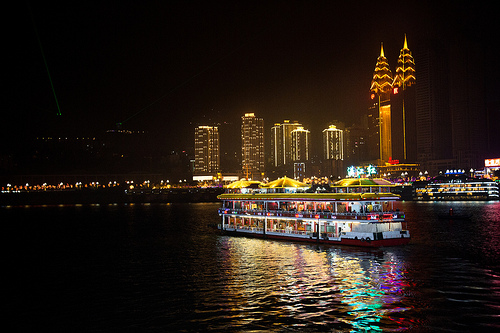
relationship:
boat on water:
[205, 157, 397, 242] [116, 240, 300, 318]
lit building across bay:
[189, 121, 220, 175] [4, 200, 497, 324]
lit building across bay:
[239, 110, 264, 178] [4, 200, 497, 324]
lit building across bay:
[269, 116, 281, 173] [4, 200, 497, 324]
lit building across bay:
[287, 123, 308, 162] [4, 200, 497, 324]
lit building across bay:
[322, 124, 344, 159] [4, 200, 497, 324]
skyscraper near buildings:
[323, 31, 427, 138] [144, 49, 423, 189]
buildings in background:
[183, 33, 439, 182] [26, 143, 482, 204]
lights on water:
[287, 241, 419, 331] [2, 233, 497, 330]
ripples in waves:
[169, 230, 499, 325] [225, 237, 424, 331]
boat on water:
[210, 168, 413, 251] [2, 204, 498, 331]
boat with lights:
[210, 168, 413, 251] [210, 167, 402, 325]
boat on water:
[210, 168, 413, 251] [173, 248, 415, 314]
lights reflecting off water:
[220, 170, 393, 195] [6, 192, 498, 329]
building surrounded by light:
[349, 35, 446, 207] [361, 10, 426, 188]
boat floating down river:
[213, 176, 410, 246] [0, 201, 499, 331]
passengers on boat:
[227, 205, 391, 225] [219, 189, 412, 250]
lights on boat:
[232, 210, 396, 220] [188, 157, 471, 284]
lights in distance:
[58, 161, 269, 215] [18, 171, 484, 198]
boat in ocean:
[214, 184, 411, 252] [52, 211, 474, 312]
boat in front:
[195, 51, 450, 256] [220, 170, 434, 200]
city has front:
[7, 37, 484, 196] [220, 170, 434, 200]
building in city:
[189, 116, 226, 185] [160, 53, 447, 219]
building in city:
[240, 110, 264, 180] [160, 53, 447, 219]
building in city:
[273, 119, 311, 178] [160, 53, 447, 219]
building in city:
[319, 124, 348, 174] [160, 53, 447, 219]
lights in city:
[1, 34, 496, 194] [7, 37, 484, 196]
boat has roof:
[209, 184, 402, 223] [217, 186, 397, 203]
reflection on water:
[227, 238, 344, 290] [106, 229, 449, 322]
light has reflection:
[223, 215, 383, 222] [227, 238, 344, 290]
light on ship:
[293, 213, 297, 217] [215, 191, 410, 244]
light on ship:
[265, 210, 270, 216] [215, 191, 410, 244]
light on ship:
[223, 208, 226, 214] [215, 191, 410, 244]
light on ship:
[367, 213, 392, 219] [215, 191, 410, 244]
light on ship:
[342, 202, 348, 209] [215, 191, 410, 244]